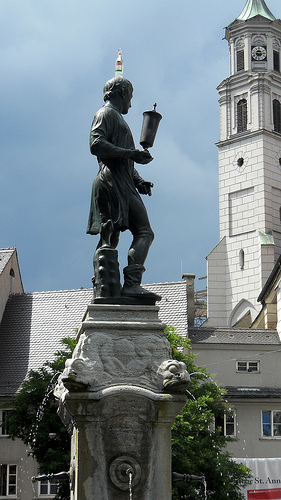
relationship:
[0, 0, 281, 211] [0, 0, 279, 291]
clouds in sky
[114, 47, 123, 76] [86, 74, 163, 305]
bottle on a statue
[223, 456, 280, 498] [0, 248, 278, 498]
sign on a building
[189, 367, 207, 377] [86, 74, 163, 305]
water coming out of statue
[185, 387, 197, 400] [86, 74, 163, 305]
water coming out of statue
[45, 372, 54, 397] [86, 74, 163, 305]
water coming out of statue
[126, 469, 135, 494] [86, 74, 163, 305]
water coming out of statue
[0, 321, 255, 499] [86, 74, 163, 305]
tree behind statue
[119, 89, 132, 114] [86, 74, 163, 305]
face on a statue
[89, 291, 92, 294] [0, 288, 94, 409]
shingle on a roof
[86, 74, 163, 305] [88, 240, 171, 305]
statue with boots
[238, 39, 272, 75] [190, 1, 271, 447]
clock on a building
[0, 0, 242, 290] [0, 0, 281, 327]
clouds in a sky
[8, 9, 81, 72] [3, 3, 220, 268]
clouds in sky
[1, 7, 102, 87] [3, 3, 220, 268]
clouds in sky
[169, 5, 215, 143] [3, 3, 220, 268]
clouds in sky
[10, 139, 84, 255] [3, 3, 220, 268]
clouds in sky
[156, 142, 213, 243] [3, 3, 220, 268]
clouds in sky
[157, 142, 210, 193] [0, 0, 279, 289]
clouds in blue sky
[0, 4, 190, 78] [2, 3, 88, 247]
clouds in sky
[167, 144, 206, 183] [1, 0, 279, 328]
white clouds in blue sky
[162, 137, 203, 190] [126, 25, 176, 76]
white clouds in blue sky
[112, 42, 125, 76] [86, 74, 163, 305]
bottle on top of statue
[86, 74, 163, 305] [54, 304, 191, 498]
statue on top of fountain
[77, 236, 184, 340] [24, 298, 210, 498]
water spraying out of fountain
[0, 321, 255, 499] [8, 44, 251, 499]
tree behind fountain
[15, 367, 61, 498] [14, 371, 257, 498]
water spraying from places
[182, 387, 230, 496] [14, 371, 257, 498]
water spraying from places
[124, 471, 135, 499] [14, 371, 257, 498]
water spraying from places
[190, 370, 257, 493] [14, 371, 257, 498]
water spraying from places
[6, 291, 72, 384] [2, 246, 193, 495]
roof on building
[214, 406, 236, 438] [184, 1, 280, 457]
window on building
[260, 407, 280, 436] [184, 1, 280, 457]
window on building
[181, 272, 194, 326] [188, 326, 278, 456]
chimney on building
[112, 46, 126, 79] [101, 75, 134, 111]
bottle on statue's head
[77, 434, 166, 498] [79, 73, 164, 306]
fountain beneath statue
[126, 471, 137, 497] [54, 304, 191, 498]
water pouring from fountain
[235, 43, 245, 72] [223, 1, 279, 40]
window near roof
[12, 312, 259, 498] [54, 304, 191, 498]
tree behind fountain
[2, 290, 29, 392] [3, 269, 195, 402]
shadow falling across roof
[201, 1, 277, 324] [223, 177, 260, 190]
tower composed of blocks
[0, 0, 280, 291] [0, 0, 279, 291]
clouds are in sky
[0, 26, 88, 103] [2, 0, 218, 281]
white clouds are in blue sky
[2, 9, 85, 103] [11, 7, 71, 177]
white clouds are in sky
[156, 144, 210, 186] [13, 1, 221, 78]
white clouds are in blue sky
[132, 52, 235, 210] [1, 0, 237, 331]
cloud in sky